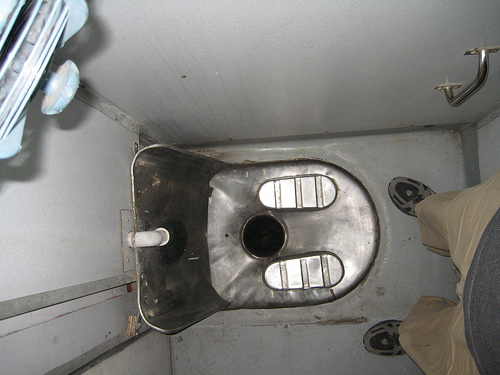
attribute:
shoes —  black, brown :
[364, 179, 432, 363]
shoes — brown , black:
[361, 181, 433, 354]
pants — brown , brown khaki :
[399, 190, 483, 367]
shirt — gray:
[455, 214, 484, 349]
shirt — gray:
[451, 211, 484, 367]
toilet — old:
[103, 129, 405, 338]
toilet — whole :
[114, 135, 395, 344]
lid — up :
[124, 139, 216, 338]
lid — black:
[111, 125, 236, 341]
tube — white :
[129, 221, 175, 254]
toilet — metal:
[124, 126, 394, 336]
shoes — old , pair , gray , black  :
[366, 177, 435, 353]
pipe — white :
[128, 210, 170, 250]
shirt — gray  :
[462, 218, 484, 370]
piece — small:
[111, 307, 145, 343]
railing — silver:
[431, 46, 494, 112]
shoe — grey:
[385, 173, 436, 211]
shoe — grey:
[361, 310, 412, 357]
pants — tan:
[400, 181, 496, 373]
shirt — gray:
[458, 202, 496, 372]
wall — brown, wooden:
[1, 73, 172, 370]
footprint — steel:
[259, 166, 338, 218]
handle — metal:
[438, 40, 495, 105]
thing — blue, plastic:
[3, 0, 99, 157]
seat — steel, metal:
[200, 156, 375, 306]